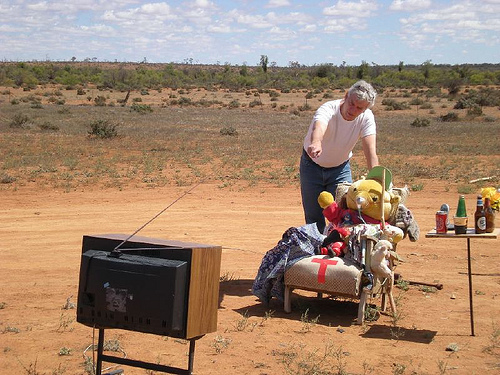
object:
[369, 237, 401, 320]
animal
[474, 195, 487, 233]
tabasco sauce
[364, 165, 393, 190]
hat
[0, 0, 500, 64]
clouds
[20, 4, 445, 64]
sky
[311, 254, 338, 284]
cross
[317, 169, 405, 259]
animal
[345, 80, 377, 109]
hair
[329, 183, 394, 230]
sunglasses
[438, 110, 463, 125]
bushes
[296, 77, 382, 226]
man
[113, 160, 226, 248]
antenna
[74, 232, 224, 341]
television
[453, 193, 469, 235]
bottles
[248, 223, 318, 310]
cloth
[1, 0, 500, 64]
sky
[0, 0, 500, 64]
blue sky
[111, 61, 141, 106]
foliage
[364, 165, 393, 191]
cap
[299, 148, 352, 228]
jeans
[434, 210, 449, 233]
can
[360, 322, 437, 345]
shadow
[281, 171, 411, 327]
chair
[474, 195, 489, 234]
bottle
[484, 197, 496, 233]
bottle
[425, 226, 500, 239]
table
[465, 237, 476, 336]
pole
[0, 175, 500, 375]
dirt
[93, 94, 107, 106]
bushels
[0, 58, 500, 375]
desert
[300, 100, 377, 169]
shirt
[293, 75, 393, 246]
guy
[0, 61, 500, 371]
ground